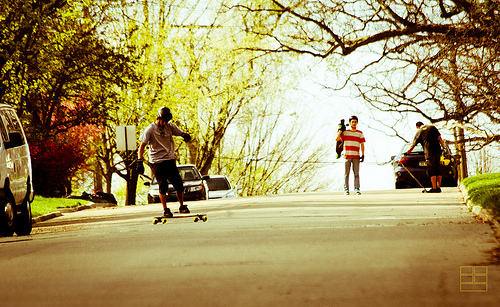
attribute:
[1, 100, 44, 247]
van — white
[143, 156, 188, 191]
shorts — black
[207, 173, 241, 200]
suv — white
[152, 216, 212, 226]
wheels — yellow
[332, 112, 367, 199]
man — white, striped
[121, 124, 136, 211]
pole — metal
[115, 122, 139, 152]
sign — metal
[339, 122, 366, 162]
shirt — red